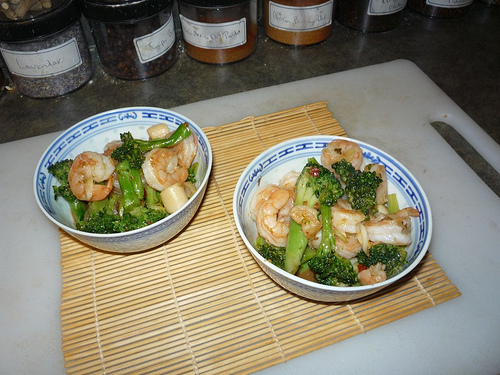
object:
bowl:
[232, 135, 432, 302]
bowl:
[32, 106, 211, 253]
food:
[48, 127, 194, 230]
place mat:
[62, 247, 248, 374]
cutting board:
[344, 59, 489, 139]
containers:
[1, 0, 92, 98]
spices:
[83, 2, 178, 79]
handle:
[430, 119, 499, 199]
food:
[257, 140, 416, 282]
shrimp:
[69, 150, 116, 203]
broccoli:
[310, 206, 359, 287]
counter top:
[341, 19, 499, 59]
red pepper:
[355, 262, 368, 272]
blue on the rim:
[385, 155, 422, 209]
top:
[82, 1, 178, 18]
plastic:
[2, 227, 60, 374]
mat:
[61, 255, 252, 375]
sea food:
[140, 135, 197, 189]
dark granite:
[434, 17, 498, 86]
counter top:
[419, 19, 497, 76]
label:
[1, 40, 82, 79]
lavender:
[14, 57, 64, 69]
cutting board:
[432, 80, 497, 375]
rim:
[101, 108, 181, 131]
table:
[2, 51, 484, 372]